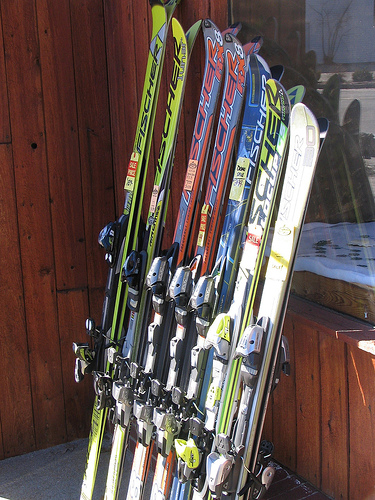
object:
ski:
[207, 100, 321, 498]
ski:
[179, 51, 289, 498]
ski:
[149, 32, 247, 499]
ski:
[126, 18, 224, 499]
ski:
[214, 78, 331, 499]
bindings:
[72, 224, 276, 496]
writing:
[135, 43, 164, 156]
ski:
[101, 16, 190, 499]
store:
[0, 0, 371, 496]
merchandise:
[199, 101, 321, 499]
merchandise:
[194, 77, 295, 499]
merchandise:
[170, 50, 268, 498]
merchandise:
[119, 23, 226, 499]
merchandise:
[74, 3, 193, 499]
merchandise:
[75, 2, 174, 499]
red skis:
[125, 17, 248, 499]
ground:
[298, 106, 331, 133]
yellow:
[166, 17, 188, 47]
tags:
[124, 151, 263, 272]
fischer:
[200, 49, 237, 217]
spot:
[310, 373, 313, 381]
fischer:
[135, 43, 162, 158]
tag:
[124, 151, 140, 191]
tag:
[196, 204, 209, 248]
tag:
[239, 223, 263, 270]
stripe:
[246, 230, 262, 246]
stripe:
[199, 213, 209, 232]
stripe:
[126, 158, 138, 178]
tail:
[116, 2, 330, 247]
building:
[0, 2, 373, 498]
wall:
[0, 0, 233, 465]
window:
[236, 0, 375, 327]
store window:
[219, 1, 372, 330]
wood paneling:
[261, 291, 375, 500]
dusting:
[2, 429, 180, 498]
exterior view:
[289, 5, 374, 283]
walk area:
[292, 221, 374, 286]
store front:
[116, 1, 373, 498]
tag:
[149, 184, 163, 216]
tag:
[228, 156, 249, 204]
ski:
[70, 1, 168, 498]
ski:
[170, 54, 294, 498]